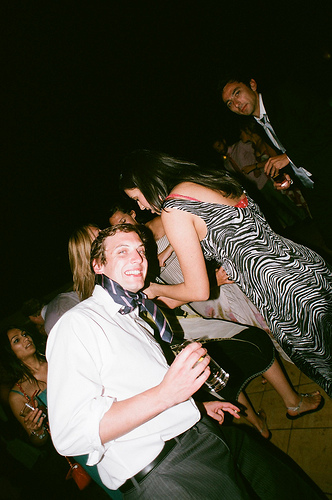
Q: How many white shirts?
A: One.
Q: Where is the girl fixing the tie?
A: In front of the guy.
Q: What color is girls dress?
A: Black and white.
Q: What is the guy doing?
A: Holding a glass.